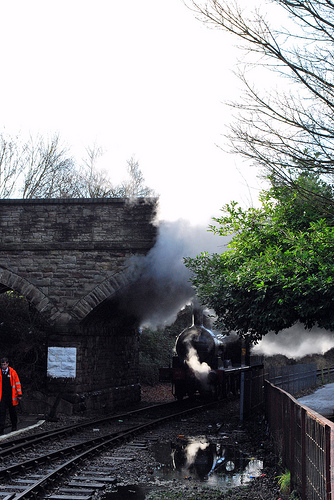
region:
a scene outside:
[22, 13, 333, 470]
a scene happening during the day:
[11, 10, 309, 493]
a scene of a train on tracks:
[14, 14, 294, 494]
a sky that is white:
[6, 4, 323, 188]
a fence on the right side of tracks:
[227, 346, 330, 494]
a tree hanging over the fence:
[184, 166, 332, 349]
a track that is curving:
[0, 387, 243, 498]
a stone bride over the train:
[1, 193, 332, 326]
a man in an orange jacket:
[0, 353, 40, 434]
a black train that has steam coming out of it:
[130, 216, 270, 420]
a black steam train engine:
[167, 300, 249, 398]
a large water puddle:
[155, 426, 255, 487]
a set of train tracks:
[0, 381, 201, 495]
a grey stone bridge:
[2, 197, 266, 418]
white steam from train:
[140, 176, 328, 354]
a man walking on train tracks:
[0, 357, 20, 426]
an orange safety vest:
[0, 366, 22, 406]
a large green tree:
[186, 183, 331, 326]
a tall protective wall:
[253, 377, 333, 497]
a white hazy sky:
[0, 0, 303, 194]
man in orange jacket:
[0, 352, 28, 433]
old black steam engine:
[148, 276, 331, 422]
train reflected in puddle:
[143, 419, 266, 498]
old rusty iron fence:
[250, 361, 331, 498]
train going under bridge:
[0, 184, 329, 424]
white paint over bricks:
[29, 329, 91, 393]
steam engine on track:
[4, 275, 333, 497]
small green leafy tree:
[168, 171, 333, 349]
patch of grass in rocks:
[264, 457, 298, 498]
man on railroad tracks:
[0, 348, 77, 498]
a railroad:
[49, 406, 182, 496]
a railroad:
[49, 425, 117, 495]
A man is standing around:
[2, 359, 26, 431]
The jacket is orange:
[3, 369, 23, 402]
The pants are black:
[0, 401, 19, 429]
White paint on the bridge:
[47, 343, 77, 378]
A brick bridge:
[2, 202, 158, 416]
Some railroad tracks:
[3, 390, 252, 494]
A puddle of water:
[158, 422, 269, 491]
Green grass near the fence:
[273, 469, 292, 490]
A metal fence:
[256, 363, 333, 497]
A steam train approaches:
[173, 309, 264, 400]